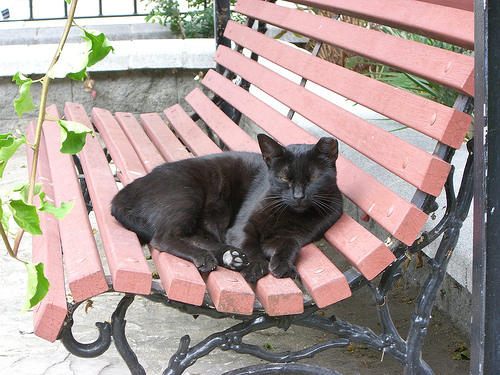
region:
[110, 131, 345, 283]
a black cat resting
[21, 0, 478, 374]
a red wooden park bench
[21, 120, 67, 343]
a red wood slat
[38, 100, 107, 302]
a red wood slat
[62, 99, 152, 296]
a red wood slat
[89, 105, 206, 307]
a red wood slat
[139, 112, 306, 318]
a red wood slat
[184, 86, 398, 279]
a red wood slat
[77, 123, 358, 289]
this is a black cat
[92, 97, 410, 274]
the cat is on the bench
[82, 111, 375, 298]
a cat sitting on a bench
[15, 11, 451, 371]
the bench is made of wood and iron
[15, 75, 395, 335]
the seat of the bench is red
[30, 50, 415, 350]
the seat is red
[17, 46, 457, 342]
the seat is curved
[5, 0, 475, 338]
the bench is made of iron and wood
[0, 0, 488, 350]
the wooden beans are painted a pastel red color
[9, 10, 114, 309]
this is a plant on a vine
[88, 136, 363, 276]
cat sitting on a bench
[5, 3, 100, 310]
the stem of a plant at left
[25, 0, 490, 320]
curved wooden bench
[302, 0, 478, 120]
plants behind the bench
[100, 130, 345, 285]
cat looking at camera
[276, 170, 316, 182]
cat's eyes look squinty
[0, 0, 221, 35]
metal fence above stone wall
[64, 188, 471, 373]
iron base for the bench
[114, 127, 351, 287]
big black house cat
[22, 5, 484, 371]
red painted wooden park bench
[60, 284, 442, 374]
black wrought iron legs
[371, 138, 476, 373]
black wrought iron bench backing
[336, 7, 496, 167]
dark green palm fronds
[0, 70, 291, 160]
grey concrete brick wall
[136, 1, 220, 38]
small leafy tree branches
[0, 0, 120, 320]
low hanging leafy green tree branch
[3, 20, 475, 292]
grey granite blocks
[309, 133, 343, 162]
stubby left ear